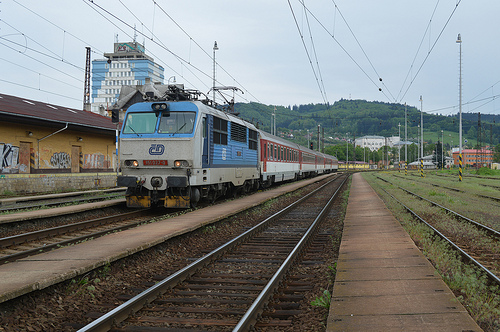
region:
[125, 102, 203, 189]
White and blue front car of a train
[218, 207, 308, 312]
Light gray metal train tracks with darker connecting metal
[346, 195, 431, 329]
Light brown colored pathway surrounded by grass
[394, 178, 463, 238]
Patchy green grass over running a metal train track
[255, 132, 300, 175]
Red and white car to a train with windows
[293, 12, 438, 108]
Dark black interconnected wires strung along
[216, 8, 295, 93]
Pale cloudless blue sky above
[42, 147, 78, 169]
Black and white graffiti on a yellow wall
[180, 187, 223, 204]
Black wheels of a train on tracks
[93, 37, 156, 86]
Tall blue and white colored building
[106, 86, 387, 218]
the train is long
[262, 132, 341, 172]
the train has many windows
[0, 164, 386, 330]
the train is on tracks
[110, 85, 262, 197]
the train engine is blue and grey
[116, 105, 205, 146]
the train has a widnshield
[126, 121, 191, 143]
the train has windshield wipers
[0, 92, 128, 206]
the building is yellow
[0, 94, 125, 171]
the building has lots of graffiti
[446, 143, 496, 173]
the building is orange with a red roof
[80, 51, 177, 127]
the building is blue and white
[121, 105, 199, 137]
the windshield of the train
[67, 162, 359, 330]
a set of train tracks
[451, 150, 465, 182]
a yellow and black striped pole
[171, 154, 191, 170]
the head lights of the train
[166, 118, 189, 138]
a black windshield wiper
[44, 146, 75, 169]
graffiti on the wall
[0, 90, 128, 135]
the roof of the building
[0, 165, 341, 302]
a gray cement sidewalk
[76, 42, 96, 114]
a metal pole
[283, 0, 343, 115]
wires in the sky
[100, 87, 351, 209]
a train on railroad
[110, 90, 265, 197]
front car is blue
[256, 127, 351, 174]
cars of train are red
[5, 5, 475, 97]
power lines on top of train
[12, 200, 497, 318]
railroad of train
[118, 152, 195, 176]
headlights of train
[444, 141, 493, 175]
a red building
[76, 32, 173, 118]
a blue building behind a train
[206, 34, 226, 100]
a light on side a train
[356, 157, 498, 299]
grass covered the railroad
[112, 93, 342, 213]
Train on the tracks.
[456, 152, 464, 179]
Black and yellow colors on bottom of post.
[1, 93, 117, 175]
Building beside the train.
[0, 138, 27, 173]
Graffiti on the wall.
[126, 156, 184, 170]
Headlights on the front of the train.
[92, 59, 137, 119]
White pyramid design on the building.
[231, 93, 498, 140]
Trees in the background.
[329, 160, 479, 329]
Concrete walkway beside the tracks.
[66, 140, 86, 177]
Door in the side of the building.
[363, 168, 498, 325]
Green grass growing in between the tracks.